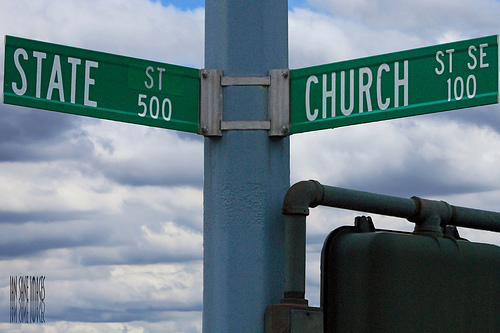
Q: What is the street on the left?
A: State.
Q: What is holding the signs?
A: A blue beam.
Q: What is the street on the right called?
A: Church.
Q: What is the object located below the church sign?
A: A crosswalk sign.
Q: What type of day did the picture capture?
A: A sunny but cloudy day.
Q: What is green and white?
A: A sign.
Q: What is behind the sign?
A: Gray cloulds.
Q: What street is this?
A: State st.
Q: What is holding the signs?
A: A metal clamp.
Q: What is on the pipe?
A: Another sign.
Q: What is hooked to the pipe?
A: A curved sign.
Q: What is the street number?
A: 100.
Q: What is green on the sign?
A: The back ground.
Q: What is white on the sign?
A: The letters.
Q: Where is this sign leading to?
A: State st.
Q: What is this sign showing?
A: Cross streets.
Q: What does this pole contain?
A: Street signs.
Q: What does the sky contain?
A: White clouds.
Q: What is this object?
A: Traffic light.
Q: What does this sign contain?
A: Address to areas.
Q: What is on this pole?
A: Street signs.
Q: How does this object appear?
A: Black in color.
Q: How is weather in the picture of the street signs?
A: Cloudy.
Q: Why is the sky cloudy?
A: Possibility of rain.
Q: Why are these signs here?
A: To indicate the streets.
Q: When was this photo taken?
A: During the daytime.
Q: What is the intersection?
A: State street and Church Street.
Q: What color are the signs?
A: Green.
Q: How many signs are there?
A: Two.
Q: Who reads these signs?
A: Drivers and pedestrians.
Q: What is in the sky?
A: Clouds.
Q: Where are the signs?
A: On a street pole.